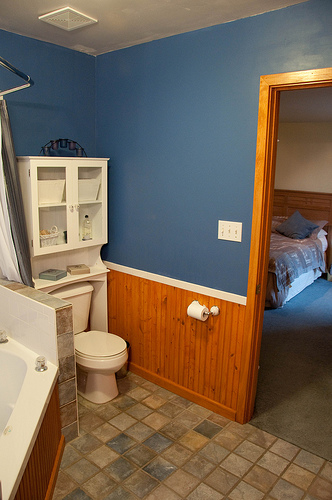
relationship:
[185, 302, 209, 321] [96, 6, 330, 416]
toilet paper hanging on wall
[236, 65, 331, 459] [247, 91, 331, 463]
doorway next to bedroom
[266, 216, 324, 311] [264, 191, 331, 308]
bedspread on top of bed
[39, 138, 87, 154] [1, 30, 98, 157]
design next to wall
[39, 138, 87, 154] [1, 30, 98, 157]
design attached to wall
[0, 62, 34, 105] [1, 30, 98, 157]
hanger attached to wall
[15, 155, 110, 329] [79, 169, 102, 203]
cupboard has window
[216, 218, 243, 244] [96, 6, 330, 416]
light switch hanging on wall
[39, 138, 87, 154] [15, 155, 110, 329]
design on top of cupboard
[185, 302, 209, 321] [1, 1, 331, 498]
toilet paper inside of bathroom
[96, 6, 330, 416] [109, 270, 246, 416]
wall has boarding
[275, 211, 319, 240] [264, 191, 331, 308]
pillow on top of bed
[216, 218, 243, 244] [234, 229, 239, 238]
light switch has switch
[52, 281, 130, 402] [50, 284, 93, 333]
toilet has toilet sink